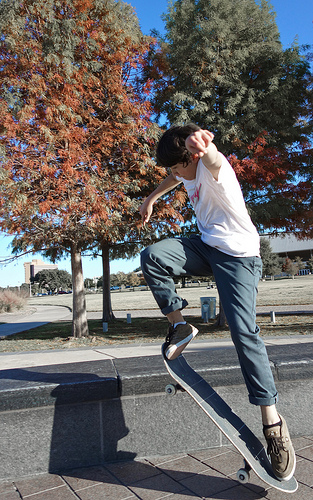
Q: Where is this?
A: This is at the road.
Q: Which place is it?
A: It is a road.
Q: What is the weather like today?
A: It is clear.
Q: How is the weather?
A: It is clear.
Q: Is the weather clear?
A: Yes, it is clear.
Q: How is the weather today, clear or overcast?
A: It is clear.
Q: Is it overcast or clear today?
A: It is clear.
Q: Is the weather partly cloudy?
A: No, it is clear.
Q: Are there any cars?
A: No, there are no cars.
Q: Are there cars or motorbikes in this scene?
A: No, there are no cars or motorbikes.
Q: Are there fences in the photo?
A: No, there are no fences.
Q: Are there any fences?
A: No, there are no fences.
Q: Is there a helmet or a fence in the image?
A: No, there are no fences or helmets.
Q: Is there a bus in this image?
A: No, there are no buses.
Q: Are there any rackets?
A: No, there are no rackets.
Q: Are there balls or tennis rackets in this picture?
A: No, there are no tennis rackets or balls.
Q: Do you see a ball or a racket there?
A: No, there are no rackets or balls.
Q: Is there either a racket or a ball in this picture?
A: No, there are no rackets or balls.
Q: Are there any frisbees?
A: No, there are no frisbees.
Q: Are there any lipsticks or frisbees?
A: No, there are no frisbees or lipsticks.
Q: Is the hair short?
A: Yes, the hair is short.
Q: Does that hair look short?
A: Yes, the hair is short.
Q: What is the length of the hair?
A: The hair is short.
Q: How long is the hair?
A: The hair is short.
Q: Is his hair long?
A: No, the hair is short.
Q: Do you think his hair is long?
A: No, the hair is short.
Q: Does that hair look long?
A: No, the hair is short.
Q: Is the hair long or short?
A: The hair is short.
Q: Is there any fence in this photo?
A: No, there are no fences.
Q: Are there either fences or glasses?
A: No, there are no fences or glasses.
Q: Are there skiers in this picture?
A: No, there are no skiers.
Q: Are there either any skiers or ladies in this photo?
A: No, there are no skiers or ladies.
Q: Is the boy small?
A: Yes, the boy is small.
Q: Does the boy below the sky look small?
A: Yes, the boy is small.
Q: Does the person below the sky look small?
A: Yes, the boy is small.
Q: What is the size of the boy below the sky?
A: The boy is small.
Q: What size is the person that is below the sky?
A: The boy is small.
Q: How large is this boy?
A: The boy is small.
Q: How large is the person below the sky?
A: The boy is small.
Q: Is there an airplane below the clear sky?
A: No, there is a boy below the sky.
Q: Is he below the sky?
A: Yes, the boy is below the sky.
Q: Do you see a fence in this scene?
A: No, there are no fences.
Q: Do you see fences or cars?
A: No, there are no fences or cars.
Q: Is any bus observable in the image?
A: No, there are no buses.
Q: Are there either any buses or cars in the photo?
A: No, there are no buses or cars.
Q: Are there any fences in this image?
A: No, there are no fences.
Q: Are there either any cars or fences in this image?
A: No, there are no fences or cars.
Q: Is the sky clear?
A: Yes, the sky is clear.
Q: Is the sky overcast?
A: No, the sky is clear.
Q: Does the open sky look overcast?
A: No, the sky is clear.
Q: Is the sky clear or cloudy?
A: The sky is clear.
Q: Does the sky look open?
A: Yes, the sky is open.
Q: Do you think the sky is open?
A: Yes, the sky is open.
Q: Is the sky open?
A: Yes, the sky is open.